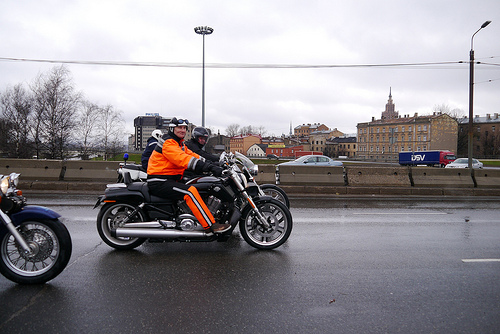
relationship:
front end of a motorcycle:
[1, 171, 74, 287] [91, 148, 293, 253]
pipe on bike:
[116, 225, 217, 237] [92, 150, 292, 250]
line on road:
[458, 255, 498, 265] [344, 196, 476, 329]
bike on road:
[92, 163, 292, 250] [0, 193, 499, 333]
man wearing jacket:
[141, 116, 231, 236] [143, 134, 205, 176]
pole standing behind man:
[191, 21, 218, 127] [141, 116, 231, 236]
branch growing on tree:
[58, 75, 73, 85] [3, 62, 133, 154]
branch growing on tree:
[37, 69, 44, 83] [3, 62, 133, 154]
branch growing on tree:
[57, 62, 64, 72] [3, 62, 133, 154]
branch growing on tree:
[59, 70, 69, 78] [3, 62, 133, 154]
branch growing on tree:
[52, 97, 71, 104] [3, 62, 133, 154]